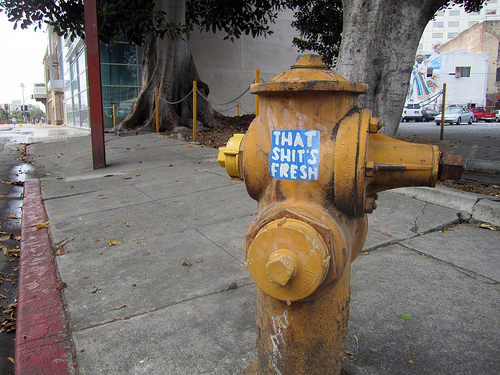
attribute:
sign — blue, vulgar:
[267, 122, 326, 187]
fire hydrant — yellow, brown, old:
[211, 41, 471, 374]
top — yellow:
[238, 49, 377, 102]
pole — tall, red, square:
[80, 1, 116, 170]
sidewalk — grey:
[19, 118, 500, 375]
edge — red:
[8, 135, 78, 374]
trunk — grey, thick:
[116, 1, 227, 132]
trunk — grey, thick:
[323, 2, 449, 149]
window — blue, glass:
[98, 29, 152, 132]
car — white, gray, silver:
[434, 104, 476, 130]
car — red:
[466, 104, 496, 126]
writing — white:
[272, 132, 317, 179]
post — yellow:
[108, 99, 121, 127]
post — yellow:
[153, 83, 162, 135]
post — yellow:
[191, 79, 199, 147]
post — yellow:
[253, 68, 265, 122]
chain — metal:
[157, 89, 194, 105]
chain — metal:
[195, 88, 249, 105]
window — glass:
[61, 48, 95, 132]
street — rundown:
[1, 122, 29, 374]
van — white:
[397, 102, 426, 123]